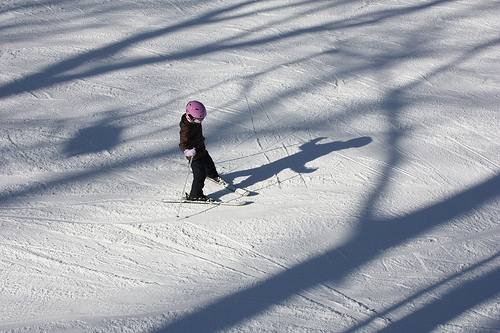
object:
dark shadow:
[3, 1, 500, 104]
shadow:
[0, 0, 103, 40]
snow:
[5, 207, 497, 329]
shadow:
[0, 146, 182, 206]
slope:
[0, 0, 500, 333]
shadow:
[205, 63, 365, 147]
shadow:
[240, 174, 500, 298]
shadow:
[334, 253, 500, 333]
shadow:
[392, 41, 500, 97]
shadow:
[349, 93, 410, 239]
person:
[178, 99, 232, 203]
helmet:
[185, 100, 208, 123]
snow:
[310, 87, 425, 189]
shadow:
[314, 0, 453, 34]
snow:
[366, 76, 460, 228]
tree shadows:
[3, 0, 500, 333]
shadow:
[60, 120, 126, 158]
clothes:
[179, 113, 220, 200]